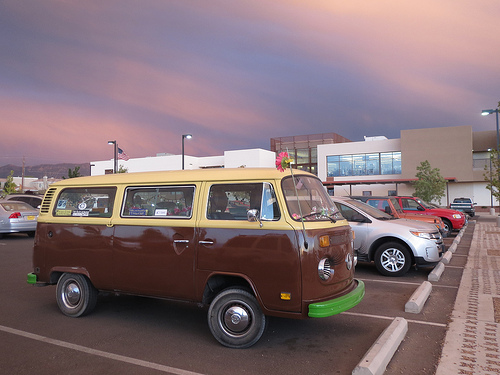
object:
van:
[27, 165, 365, 352]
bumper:
[308, 278, 367, 318]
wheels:
[56, 272, 100, 320]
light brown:
[35, 167, 351, 230]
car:
[265, 194, 445, 278]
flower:
[275, 149, 294, 171]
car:
[341, 194, 447, 236]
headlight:
[319, 257, 338, 281]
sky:
[1, 0, 500, 166]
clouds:
[1, 93, 228, 167]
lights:
[391, 152, 401, 160]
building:
[314, 124, 500, 212]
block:
[352, 315, 413, 374]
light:
[185, 134, 193, 140]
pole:
[181, 133, 188, 170]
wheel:
[208, 286, 269, 350]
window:
[120, 184, 202, 220]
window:
[381, 151, 394, 175]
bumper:
[27, 270, 39, 284]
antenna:
[285, 147, 311, 250]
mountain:
[1, 162, 91, 185]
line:
[1, 321, 206, 374]